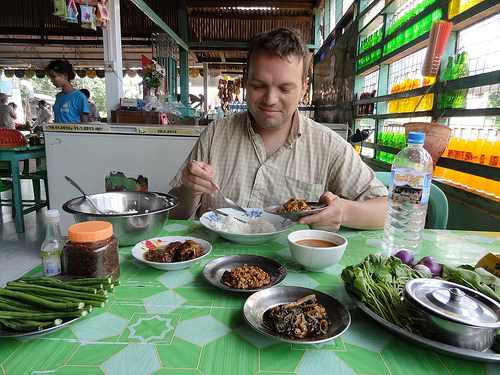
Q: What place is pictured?
A: It is a restaurant.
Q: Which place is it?
A: It is a restaurant.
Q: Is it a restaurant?
A: Yes, it is a restaurant.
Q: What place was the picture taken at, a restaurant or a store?
A: It was taken at a restaurant.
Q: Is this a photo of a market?
A: No, the picture is showing a restaurant.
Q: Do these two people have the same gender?
A: No, they are both male and female.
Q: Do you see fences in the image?
A: No, there are no fences.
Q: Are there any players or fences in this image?
A: No, there are no fences or players.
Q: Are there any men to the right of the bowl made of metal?
A: Yes, there is a man to the right of the bowl.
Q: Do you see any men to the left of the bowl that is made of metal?
A: No, the man is to the right of the bowl.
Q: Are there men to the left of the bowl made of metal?
A: No, the man is to the right of the bowl.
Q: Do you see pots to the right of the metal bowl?
A: No, there is a man to the right of the bowl.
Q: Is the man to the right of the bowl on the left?
A: Yes, the man is to the right of the bowl.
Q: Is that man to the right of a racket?
A: No, the man is to the right of the bowl.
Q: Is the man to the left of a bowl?
A: No, the man is to the right of a bowl.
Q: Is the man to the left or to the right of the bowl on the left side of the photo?
A: The man is to the right of the bowl.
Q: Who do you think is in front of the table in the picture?
A: The man is in front of the table.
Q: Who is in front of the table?
A: The man is in front of the table.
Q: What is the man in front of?
A: The man is in front of the table.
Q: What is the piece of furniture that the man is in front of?
A: The piece of furniture is a table.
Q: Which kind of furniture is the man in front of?
A: The man is in front of the table.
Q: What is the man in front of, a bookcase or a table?
A: The man is in front of a table.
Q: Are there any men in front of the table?
A: Yes, there is a man in front of the table.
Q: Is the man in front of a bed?
A: No, the man is in front of the table.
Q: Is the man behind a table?
A: No, the man is in front of a table.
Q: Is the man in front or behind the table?
A: The man is in front of the table.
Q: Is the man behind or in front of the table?
A: The man is in front of the table.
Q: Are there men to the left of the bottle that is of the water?
A: Yes, there is a man to the left of the bottle.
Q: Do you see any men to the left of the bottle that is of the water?
A: Yes, there is a man to the left of the bottle.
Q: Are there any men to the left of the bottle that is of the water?
A: Yes, there is a man to the left of the bottle.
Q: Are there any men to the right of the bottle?
A: No, the man is to the left of the bottle.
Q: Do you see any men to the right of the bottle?
A: No, the man is to the left of the bottle.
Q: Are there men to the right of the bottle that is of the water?
A: No, the man is to the left of the bottle.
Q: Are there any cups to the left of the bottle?
A: No, there is a man to the left of the bottle.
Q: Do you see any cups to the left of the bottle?
A: No, there is a man to the left of the bottle.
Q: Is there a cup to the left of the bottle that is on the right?
A: No, there is a man to the left of the bottle.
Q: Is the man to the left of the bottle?
A: Yes, the man is to the left of the bottle.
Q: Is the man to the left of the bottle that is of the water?
A: Yes, the man is to the left of the bottle.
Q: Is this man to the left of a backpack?
A: No, the man is to the left of the bottle.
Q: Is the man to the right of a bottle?
A: No, the man is to the left of a bottle.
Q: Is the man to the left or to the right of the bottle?
A: The man is to the left of the bottle.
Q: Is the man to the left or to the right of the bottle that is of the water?
A: The man is to the left of the bottle.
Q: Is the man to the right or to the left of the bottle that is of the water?
A: The man is to the left of the bottle.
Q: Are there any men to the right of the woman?
A: Yes, there is a man to the right of the woman.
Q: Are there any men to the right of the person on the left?
A: Yes, there is a man to the right of the woman.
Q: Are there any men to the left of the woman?
A: No, the man is to the right of the woman.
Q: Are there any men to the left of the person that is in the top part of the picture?
A: No, the man is to the right of the woman.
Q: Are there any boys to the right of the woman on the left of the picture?
A: No, there is a man to the right of the woman.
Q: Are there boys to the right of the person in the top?
A: No, there is a man to the right of the woman.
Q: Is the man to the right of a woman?
A: Yes, the man is to the right of a woman.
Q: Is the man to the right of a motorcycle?
A: No, the man is to the right of a woman.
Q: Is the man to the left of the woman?
A: No, the man is to the right of the woman.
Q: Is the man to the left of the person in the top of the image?
A: No, the man is to the right of the woman.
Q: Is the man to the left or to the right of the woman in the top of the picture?
A: The man is to the right of the woman.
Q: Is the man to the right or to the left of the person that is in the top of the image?
A: The man is to the right of the woman.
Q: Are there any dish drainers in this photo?
A: No, there are no dish drainers.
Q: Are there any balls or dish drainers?
A: No, there are no dish drainers or balls.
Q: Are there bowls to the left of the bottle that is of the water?
A: Yes, there is a bowl to the left of the bottle.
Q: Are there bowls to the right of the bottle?
A: No, the bowl is to the left of the bottle.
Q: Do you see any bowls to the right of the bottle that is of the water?
A: No, the bowl is to the left of the bottle.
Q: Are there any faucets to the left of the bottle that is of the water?
A: No, there is a bowl to the left of the bottle.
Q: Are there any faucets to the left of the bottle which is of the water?
A: No, there is a bowl to the left of the bottle.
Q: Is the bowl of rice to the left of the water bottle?
A: Yes, the bowl is to the left of the bottle.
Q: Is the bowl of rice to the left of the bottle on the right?
A: Yes, the bowl is to the left of the bottle.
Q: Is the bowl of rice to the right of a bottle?
A: No, the bowl is to the left of a bottle.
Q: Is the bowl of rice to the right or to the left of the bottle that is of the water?
A: The bowl is to the left of the bottle.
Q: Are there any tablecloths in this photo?
A: Yes, there is a tablecloth.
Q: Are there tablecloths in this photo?
A: Yes, there is a tablecloth.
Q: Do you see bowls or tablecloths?
A: Yes, there is a tablecloth.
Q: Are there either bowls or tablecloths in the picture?
A: Yes, there is a tablecloth.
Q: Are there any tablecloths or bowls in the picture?
A: Yes, there is a tablecloth.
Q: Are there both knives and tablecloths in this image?
A: No, there is a tablecloth but no knives.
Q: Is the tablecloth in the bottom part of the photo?
A: Yes, the tablecloth is in the bottom of the image.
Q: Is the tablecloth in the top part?
A: No, the tablecloth is in the bottom of the image.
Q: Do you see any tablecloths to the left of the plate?
A: Yes, there is a tablecloth to the left of the plate.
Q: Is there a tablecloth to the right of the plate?
A: No, the tablecloth is to the left of the plate.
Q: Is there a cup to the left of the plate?
A: No, there is a tablecloth to the left of the plate.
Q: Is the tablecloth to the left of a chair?
A: No, the tablecloth is to the left of a plate.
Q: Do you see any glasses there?
A: No, there are no glasses.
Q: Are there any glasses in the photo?
A: No, there are no glasses.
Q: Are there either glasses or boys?
A: No, there are no glasses or boys.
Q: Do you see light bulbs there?
A: No, there are no light bulbs.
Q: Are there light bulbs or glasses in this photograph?
A: No, there are no light bulbs or glasses.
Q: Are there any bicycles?
A: No, there are no bicycles.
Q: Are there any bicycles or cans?
A: No, there are no bicycles or cans.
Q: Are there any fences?
A: No, there are no fences.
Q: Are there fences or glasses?
A: No, there are no fences or glasses.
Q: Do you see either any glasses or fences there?
A: No, there are no fences or glasses.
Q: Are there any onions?
A: Yes, there are onions.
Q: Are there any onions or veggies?
A: Yes, there are onions.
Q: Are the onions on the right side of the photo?
A: Yes, the onions are on the right of the image.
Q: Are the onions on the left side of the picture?
A: No, the onions are on the right of the image.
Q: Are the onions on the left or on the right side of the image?
A: The onions are on the right of the image.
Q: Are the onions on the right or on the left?
A: The onions are on the right of the image.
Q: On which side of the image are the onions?
A: The onions are on the right of the image.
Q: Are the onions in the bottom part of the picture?
A: Yes, the onions are in the bottom of the image.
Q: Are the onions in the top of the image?
A: No, the onions are in the bottom of the image.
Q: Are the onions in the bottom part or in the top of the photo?
A: The onions are in the bottom of the image.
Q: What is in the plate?
A: The onions are in the plate.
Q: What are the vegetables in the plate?
A: The vegetables are onions.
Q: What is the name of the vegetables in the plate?
A: The vegetables are onions.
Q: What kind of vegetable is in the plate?
A: The vegetables are onions.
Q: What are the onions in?
A: The onions are in the plate.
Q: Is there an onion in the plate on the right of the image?
A: Yes, there are onions in the plate.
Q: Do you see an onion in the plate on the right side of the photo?
A: Yes, there are onions in the plate.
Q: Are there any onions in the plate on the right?
A: Yes, there are onions in the plate.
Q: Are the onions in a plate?
A: Yes, the onions are in a plate.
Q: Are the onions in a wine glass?
A: No, the onions are in a plate.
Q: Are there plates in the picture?
A: Yes, there is a plate.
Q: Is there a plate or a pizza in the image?
A: Yes, there is a plate.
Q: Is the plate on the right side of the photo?
A: Yes, the plate is on the right of the image.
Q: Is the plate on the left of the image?
A: No, the plate is on the right of the image.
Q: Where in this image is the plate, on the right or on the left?
A: The plate is on the right of the image.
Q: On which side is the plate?
A: The plate is on the right of the image.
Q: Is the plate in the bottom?
A: Yes, the plate is in the bottom of the image.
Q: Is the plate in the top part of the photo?
A: No, the plate is in the bottom of the image.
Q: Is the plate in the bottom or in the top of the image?
A: The plate is in the bottom of the image.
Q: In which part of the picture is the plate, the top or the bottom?
A: The plate is in the bottom of the image.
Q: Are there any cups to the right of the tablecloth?
A: No, there is a plate to the right of the tablecloth.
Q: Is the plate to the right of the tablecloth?
A: Yes, the plate is to the right of the tablecloth.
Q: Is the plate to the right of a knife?
A: No, the plate is to the right of the tablecloth.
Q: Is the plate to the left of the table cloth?
A: No, the plate is to the right of the table cloth.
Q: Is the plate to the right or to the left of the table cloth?
A: The plate is to the right of the table cloth.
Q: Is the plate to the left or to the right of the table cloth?
A: The plate is to the right of the table cloth.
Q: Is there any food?
A: Yes, there is food.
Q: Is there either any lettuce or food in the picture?
A: Yes, there is food.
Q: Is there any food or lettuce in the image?
A: Yes, there is food.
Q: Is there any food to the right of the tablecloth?
A: Yes, there is food to the right of the tablecloth.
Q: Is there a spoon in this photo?
A: Yes, there is a spoon.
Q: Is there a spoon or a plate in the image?
A: Yes, there is a spoon.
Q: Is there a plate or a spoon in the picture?
A: Yes, there is a spoon.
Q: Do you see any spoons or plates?
A: Yes, there is a spoon.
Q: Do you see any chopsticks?
A: No, there are no chopsticks.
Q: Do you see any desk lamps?
A: No, there are no desk lamps.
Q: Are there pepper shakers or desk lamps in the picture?
A: No, there are no desk lamps or pepper shakers.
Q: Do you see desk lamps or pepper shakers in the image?
A: No, there are no desk lamps or pepper shakers.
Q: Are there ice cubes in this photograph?
A: No, there are no ice cubes.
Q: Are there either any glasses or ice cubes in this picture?
A: No, there are no ice cubes or glasses.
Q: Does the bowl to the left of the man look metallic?
A: Yes, the bowl is metallic.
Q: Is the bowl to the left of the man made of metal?
A: Yes, the bowl is made of metal.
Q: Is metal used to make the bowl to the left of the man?
A: Yes, the bowl is made of metal.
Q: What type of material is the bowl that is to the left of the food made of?
A: The bowl is made of metal.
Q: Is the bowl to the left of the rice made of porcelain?
A: No, the bowl is made of metal.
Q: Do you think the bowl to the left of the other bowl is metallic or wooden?
A: The bowl is metallic.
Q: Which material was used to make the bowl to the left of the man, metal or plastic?
A: The bowl is made of metal.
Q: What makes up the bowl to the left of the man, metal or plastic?
A: The bowl is made of metal.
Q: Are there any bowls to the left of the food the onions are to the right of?
A: Yes, there is a bowl to the left of the food.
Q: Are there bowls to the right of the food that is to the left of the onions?
A: No, the bowl is to the left of the food.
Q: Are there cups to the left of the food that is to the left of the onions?
A: No, there is a bowl to the left of the food.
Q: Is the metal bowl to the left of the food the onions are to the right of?
A: Yes, the bowl is to the left of the food.